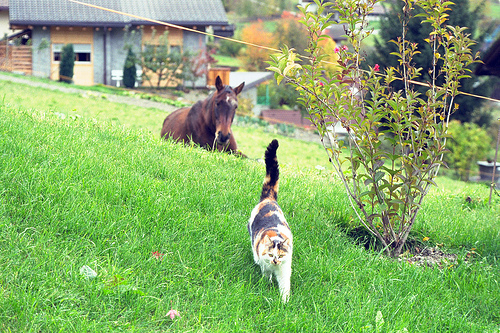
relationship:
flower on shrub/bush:
[369, 60, 380, 74] [264, 0, 484, 259]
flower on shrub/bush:
[333, 41, 347, 56] [264, 0, 484, 259]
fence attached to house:
[0, 43, 34, 74] [8, 0, 230, 101]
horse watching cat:
[144, 76, 247, 164] [249, 132, 298, 297]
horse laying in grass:
[159, 74, 259, 161] [1, 66, 483, 331]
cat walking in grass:
[246, 136, 293, 305] [42, 139, 229, 310]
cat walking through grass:
[246, 135, 305, 305] [1, 66, 483, 331]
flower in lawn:
[153, 249, 162, 262] [2, 78, 497, 331]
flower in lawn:
[163, 307, 180, 319] [2, 78, 497, 331]